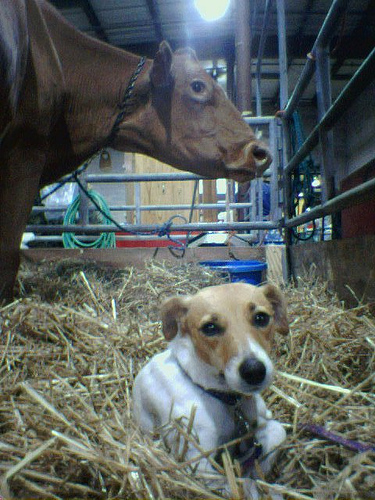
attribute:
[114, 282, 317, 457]
puppy — Tan, white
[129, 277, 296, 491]
dog — little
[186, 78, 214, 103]
cow eye — black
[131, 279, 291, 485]
little dog — white, light brown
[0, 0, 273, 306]
cow — reddish brown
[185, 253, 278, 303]
bucket — blue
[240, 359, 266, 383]
nose — black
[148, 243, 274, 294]
bucket — blue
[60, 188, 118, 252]
hose — green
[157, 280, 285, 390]
head — brown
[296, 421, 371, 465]
leash — purple